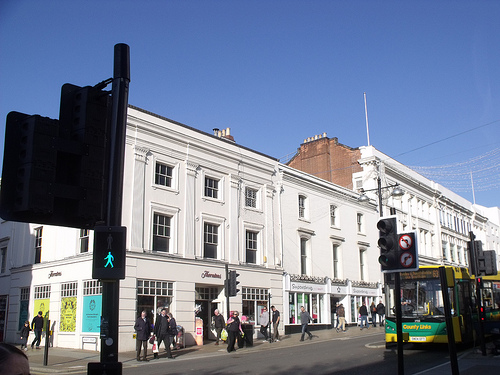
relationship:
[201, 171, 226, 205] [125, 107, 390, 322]
window on building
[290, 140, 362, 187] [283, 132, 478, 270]
brown wall of building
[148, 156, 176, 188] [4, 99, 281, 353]
window on building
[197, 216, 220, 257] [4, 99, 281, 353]
window on building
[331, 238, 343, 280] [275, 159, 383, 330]
window on building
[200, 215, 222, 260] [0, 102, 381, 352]
window on building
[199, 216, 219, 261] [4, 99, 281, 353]
window in building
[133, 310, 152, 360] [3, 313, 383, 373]
person walking on sidewalk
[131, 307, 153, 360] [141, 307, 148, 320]
person has head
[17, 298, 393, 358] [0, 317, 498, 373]
people standing on street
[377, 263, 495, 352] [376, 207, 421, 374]
bus near street light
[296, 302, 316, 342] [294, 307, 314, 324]
man wearing jacket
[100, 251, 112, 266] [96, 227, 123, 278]
green man on traffic signal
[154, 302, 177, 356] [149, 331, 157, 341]
man has hand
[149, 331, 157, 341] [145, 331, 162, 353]
hand carrying bag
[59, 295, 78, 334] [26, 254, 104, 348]
poster hanging on wall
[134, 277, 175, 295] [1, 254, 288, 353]
windows on store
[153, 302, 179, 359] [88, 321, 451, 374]
man standing on street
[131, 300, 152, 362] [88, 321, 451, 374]
man standing on street